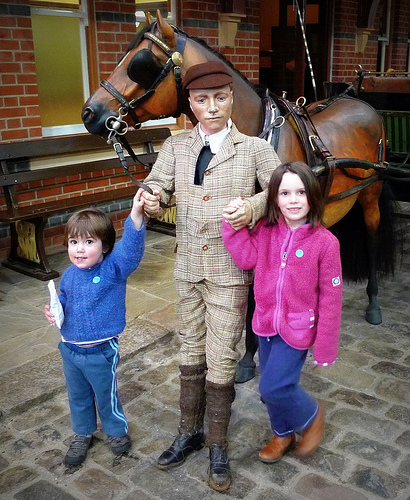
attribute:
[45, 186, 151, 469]
boy — small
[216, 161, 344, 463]
girl — small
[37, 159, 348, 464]
children — small, young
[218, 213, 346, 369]
jacket — pink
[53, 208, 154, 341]
sweater — blue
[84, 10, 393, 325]
horse — brown, black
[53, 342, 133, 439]
pants — blue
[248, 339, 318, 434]
pants — blue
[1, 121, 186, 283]
bench — wooden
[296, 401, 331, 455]
shoe — leather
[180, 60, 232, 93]
hat — brown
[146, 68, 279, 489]
statue — man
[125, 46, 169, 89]
patch — black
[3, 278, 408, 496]
street — brick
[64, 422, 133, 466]
shoes — tennis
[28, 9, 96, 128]
glass — frosted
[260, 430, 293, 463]
shoe — leather\